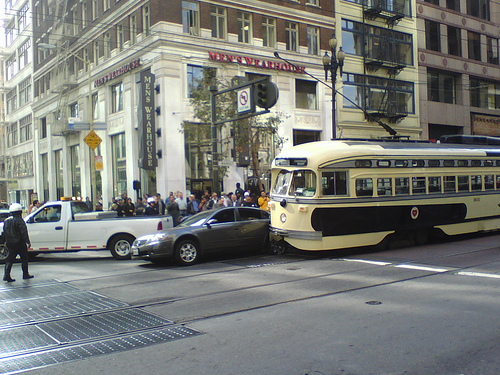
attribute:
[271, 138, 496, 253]
trolley — yellow, black, white, cream colored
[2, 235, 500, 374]
street — paved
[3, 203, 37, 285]
officer — standing, walking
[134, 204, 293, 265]
car — silver, gray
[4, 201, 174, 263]
truck — white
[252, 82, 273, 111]
lights — black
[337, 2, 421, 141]
building — yellow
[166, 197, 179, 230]
person — standing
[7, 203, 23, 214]
helmet — white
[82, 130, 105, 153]
sign — yellow, diamond shaped